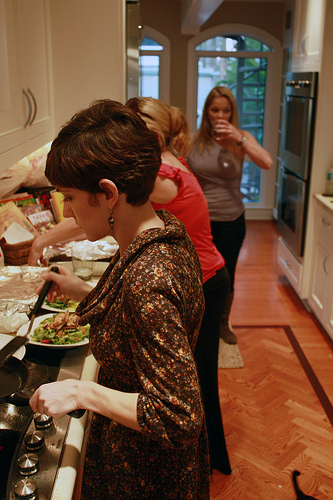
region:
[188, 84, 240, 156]
a woman's long blonde hair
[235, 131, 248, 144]
a woman's wristwatch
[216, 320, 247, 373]
part of a beige rug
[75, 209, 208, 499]
part of a woman's brown shirt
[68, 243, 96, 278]
a small glass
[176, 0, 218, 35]
part of a white ceiling beam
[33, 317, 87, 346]
a green salad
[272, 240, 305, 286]
a long white drawer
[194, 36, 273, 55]
a small window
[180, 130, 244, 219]
part of a woman's gray shirt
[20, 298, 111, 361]
white plate with food on it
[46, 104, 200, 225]
woman has short brown hair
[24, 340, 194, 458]
woman is holding a pan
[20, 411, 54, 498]
knobs on the stove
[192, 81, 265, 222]
woman is drinking from a cup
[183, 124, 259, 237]
woman has gray shirt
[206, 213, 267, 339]
woman is wearing black pants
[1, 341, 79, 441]
the pan is black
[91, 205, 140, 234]
woman is wearing earrings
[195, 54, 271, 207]
a long window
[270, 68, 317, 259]
a tall gray wall oven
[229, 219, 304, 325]
part of a hardwood floor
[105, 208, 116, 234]
a woman's long earring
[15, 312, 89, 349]
a white plate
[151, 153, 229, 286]
a woman's tank top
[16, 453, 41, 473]
a gray oven knob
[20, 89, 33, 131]
a gray cabinet handle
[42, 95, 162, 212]
a woman's short cut brown hair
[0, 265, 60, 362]
part of a black spatula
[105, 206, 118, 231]
a long, dangling earring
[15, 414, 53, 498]
knobs on a stove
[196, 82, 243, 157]
a woman with long blonde hair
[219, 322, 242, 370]
a rug on the floor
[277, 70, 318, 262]
a double oven in the wall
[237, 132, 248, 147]
a silver wrist watch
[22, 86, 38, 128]
curved handles on a cabinet door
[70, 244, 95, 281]
a glass of water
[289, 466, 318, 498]
a tail of a black animal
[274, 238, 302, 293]
a drawer under the oven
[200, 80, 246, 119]
Person has blonde hair.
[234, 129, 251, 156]
Person is wearing watch on wrist.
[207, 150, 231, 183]
Person wearing gray shirt.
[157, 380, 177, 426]
Person wearing brown floral print shirt.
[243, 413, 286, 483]
Hard wood floors in room.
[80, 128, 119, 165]
Person has short brown hair.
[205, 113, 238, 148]
Person holding glass in hand.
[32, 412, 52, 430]
stove has a knob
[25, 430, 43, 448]
stove has a knob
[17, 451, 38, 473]
stove has a knob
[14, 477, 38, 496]
stove has a knob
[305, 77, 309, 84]
stove has a knob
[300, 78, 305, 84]
stove has a knob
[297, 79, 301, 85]
stove has a knob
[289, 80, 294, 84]
stove has a knob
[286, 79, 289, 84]
stove has a knob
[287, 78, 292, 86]
stove has a knob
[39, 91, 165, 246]
A woman has short brown hair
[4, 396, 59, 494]
Knobs on a stove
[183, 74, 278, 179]
A woman drinking from a glass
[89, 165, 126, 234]
Dangling earring on an ear